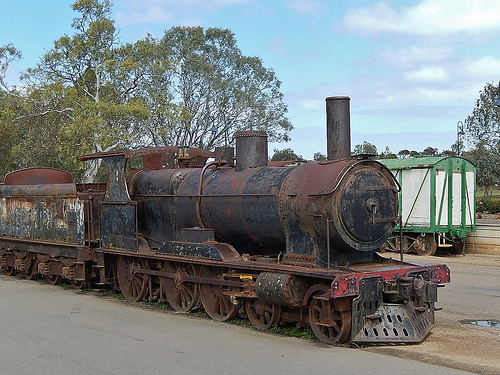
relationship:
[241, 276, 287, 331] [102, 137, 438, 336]
wheel on train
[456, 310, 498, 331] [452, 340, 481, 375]
puddle on ground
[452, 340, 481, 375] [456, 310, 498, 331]
ground with puddle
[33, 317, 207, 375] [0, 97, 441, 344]
road with train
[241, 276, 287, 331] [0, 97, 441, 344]
wheel on train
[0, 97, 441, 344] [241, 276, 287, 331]
train with wheel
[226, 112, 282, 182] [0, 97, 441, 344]
chute on train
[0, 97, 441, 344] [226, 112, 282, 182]
train with chute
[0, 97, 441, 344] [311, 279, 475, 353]
train with grill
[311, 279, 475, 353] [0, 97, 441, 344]
grill on train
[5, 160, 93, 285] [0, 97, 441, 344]
car of train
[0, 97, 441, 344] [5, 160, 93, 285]
train with car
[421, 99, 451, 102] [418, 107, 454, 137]
cloud in sky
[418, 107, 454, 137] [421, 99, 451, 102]
sky with cloud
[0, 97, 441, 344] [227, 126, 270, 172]
train with chute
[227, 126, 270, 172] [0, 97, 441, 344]
chute on train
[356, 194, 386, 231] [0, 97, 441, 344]
knob on train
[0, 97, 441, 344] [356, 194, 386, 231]
train with knob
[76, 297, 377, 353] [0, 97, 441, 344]
grass under train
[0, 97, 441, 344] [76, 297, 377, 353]
train over grass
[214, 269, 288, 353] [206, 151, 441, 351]
wheel of a train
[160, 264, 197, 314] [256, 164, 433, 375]
wheel of a train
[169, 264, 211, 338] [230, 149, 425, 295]
wheel of a train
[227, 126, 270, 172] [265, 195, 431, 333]
chute smoke pipe of a train